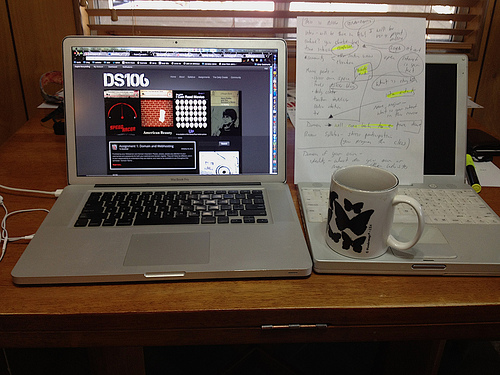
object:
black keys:
[134, 217, 200, 224]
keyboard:
[74, 190, 268, 227]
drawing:
[334, 201, 375, 235]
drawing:
[342, 231, 366, 253]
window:
[92, 0, 275, 28]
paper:
[294, 16, 425, 184]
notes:
[302, 15, 422, 168]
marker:
[465, 154, 481, 193]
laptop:
[296, 53, 500, 277]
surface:
[0, 122, 499, 315]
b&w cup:
[325, 166, 424, 260]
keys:
[78, 213, 108, 219]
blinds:
[90, 8, 469, 22]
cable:
[0, 198, 51, 263]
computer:
[9, 37, 312, 284]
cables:
[0, 184, 64, 196]